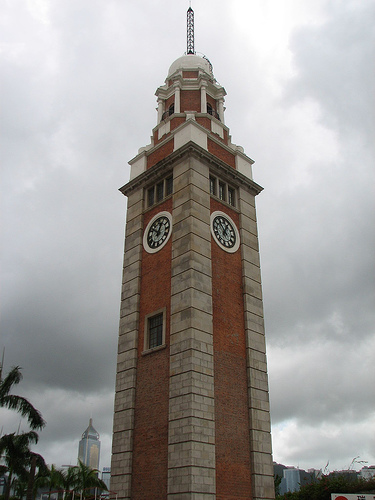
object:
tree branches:
[0, 346, 109, 499]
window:
[209, 168, 238, 213]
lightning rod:
[186, 3, 195, 54]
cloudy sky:
[0, 0, 375, 475]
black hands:
[156, 218, 164, 234]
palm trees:
[0, 345, 109, 499]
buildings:
[108, 0, 275, 498]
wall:
[140, 201, 170, 499]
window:
[143, 171, 176, 211]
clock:
[142, 210, 240, 254]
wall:
[210, 197, 257, 499]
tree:
[0, 365, 108, 499]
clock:
[208, 208, 244, 255]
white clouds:
[292, 118, 324, 147]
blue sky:
[263, 32, 289, 57]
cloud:
[0, 0, 374, 470]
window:
[141, 307, 167, 356]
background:
[2, 0, 375, 499]